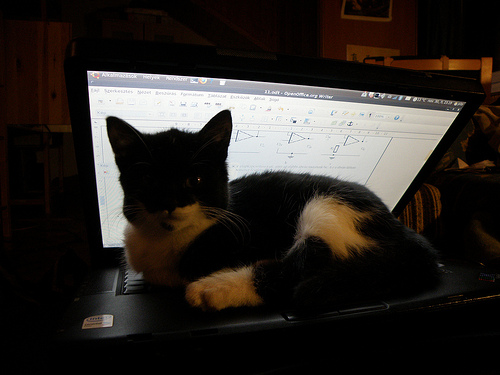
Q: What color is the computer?
A: Black.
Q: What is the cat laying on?
A: The computer.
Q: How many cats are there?
A: One.